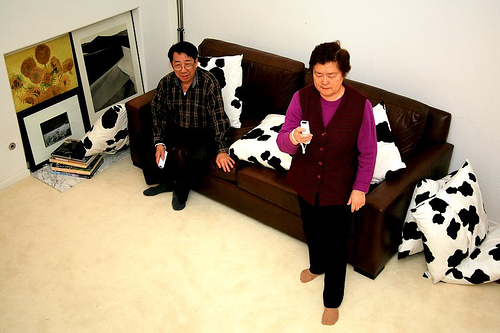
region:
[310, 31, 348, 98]
head of a person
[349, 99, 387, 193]
arm of a person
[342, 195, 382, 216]
hand of a person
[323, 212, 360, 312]
leg of a person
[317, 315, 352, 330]
feet of a person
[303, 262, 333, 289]
feet of a person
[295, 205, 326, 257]
leg of a person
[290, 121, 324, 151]
hand of a person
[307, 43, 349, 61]
hair of a person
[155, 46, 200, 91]
head of a person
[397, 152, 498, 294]
three cushions on the floor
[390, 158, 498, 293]
the cushions are white and black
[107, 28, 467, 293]
a couch color brown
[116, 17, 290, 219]
man sits on a couch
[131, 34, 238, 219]
man holds a game control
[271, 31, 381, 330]
woman holds a game control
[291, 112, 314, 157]
a white game control on hand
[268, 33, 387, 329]
woman wears a purple top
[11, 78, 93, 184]
a picture on the floor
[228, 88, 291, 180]
cushion on the couch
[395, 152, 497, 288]
Black and white pillows.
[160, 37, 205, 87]
Man with black hair and glasses.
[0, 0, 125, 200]
Pictures, books and a pillow sitting on the floor.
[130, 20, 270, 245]
Man sitting on a brown sofa.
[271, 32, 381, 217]
Person holding a cell phone.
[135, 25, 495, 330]
Two people with a brown sofa and pillows.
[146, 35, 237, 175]
Man wearing a flannel shirt.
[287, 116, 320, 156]
Hand holding a white cell phone.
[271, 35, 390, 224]
Person wearing dark vest and purple shirt.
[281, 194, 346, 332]
Dark pants and bare feet on beige floor.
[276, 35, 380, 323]
Woman holding a Wii controller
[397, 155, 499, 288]
Two cow patterned pillows on the floor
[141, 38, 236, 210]
Man holding a Wii controller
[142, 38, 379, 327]
Two people playing video games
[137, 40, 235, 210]
Man sitting on a couch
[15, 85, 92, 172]
Black and white photo in a black frame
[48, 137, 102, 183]
Stack of books on the ground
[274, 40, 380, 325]
Woman wearing a red vest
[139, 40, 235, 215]
Man wearing a plaid shirt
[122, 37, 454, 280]
Brown leather couch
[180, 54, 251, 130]
a pillow with a black and white pattern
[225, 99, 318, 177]
a pillow with a black and white pattern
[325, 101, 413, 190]
a pillow with a black and white pattern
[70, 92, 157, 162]
a pillow with a black and white pattern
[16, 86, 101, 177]
a black and white painting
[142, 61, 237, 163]
a man with a black striped shirt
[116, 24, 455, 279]
a brown sofa on a cream carpet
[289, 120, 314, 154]
a woman holding a wiimote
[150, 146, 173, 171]
a man holding a wiimote